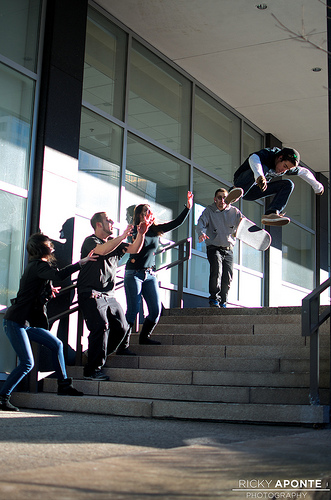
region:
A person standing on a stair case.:
[188, 168, 250, 324]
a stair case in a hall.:
[28, 280, 329, 453]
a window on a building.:
[65, 143, 123, 332]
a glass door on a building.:
[2, 30, 54, 306]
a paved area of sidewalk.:
[1, 395, 330, 498]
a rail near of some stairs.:
[250, 270, 328, 374]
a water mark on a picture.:
[214, 468, 329, 498]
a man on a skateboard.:
[227, 136, 326, 260]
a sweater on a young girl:
[120, 176, 197, 280]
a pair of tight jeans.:
[114, 256, 166, 342]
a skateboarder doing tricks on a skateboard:
[219, 142, 325, 254]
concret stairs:
[35, 298, 329, 428]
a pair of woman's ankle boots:
[0, 375, 84, 412]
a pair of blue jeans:
[2, 321, 71, 396]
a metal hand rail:
[9, 233, 201, 351]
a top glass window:
[187, 100, 244, 184]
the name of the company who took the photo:
[229, 475, 324, 498]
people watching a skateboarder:
[0, 189, 194, 410]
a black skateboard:
[229, 217, 274, 251]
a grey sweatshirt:
[194, 202, 250, 250]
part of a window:
[213, 114, 221, 117]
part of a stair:
[182, 394, 204, 420]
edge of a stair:
[142, 389, 159, 418]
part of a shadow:
[155, 426, 165, 432]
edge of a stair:
[197, 414, 202, 423]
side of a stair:
[144, 403, 154, 417]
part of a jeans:
[93, 359, 101, 372]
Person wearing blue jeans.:
[256, 176, 315, 228]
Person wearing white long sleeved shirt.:
[241, 125, 282, 211]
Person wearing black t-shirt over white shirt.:
[244, 136, 272, 182]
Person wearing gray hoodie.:
[201, 175, 229, 248]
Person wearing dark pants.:
[198, 243, 240, 291]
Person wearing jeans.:
[122, 272, 162, 319]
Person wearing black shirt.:
[134, 226, 156, 265]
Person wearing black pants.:
[85, 290, 124, 348]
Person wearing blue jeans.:
[6, 323, 76, 384]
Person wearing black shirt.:
[16, 295, 62, 325]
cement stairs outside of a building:
[30, 295, 330, 430]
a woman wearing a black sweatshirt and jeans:
[0, 234, 77, 411]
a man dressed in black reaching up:
[78, 212, 138, 373]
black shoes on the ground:
[2, 379, 85, 417]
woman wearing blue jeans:
[126, 266, 158, 344]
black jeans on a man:
[204, 247, 240, 299]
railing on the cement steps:
[294, 275, 330, 412]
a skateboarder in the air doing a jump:
[228, 131, 325, 231]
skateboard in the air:
[235, 219, 275, 256]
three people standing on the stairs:
[4, 179, 200, 413]